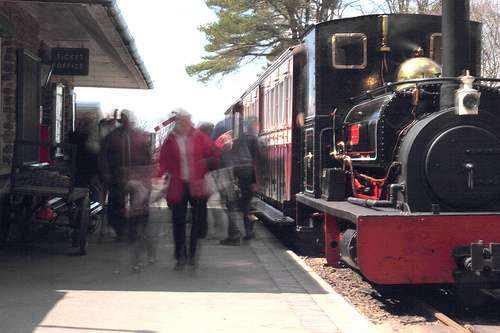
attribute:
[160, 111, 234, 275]
lady — blurred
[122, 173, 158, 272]
child — blurred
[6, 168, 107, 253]
bench — park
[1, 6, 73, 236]
wall — brick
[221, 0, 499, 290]
red — black, locomotive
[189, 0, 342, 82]
tree — tall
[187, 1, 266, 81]
leaves — green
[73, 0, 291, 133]
sky — bright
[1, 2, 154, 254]
building — ticket office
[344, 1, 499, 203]
steam egine — black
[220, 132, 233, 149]
hand — pointing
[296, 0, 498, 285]
train engine — vintage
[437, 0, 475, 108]
smoke stack — black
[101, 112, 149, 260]
pedestrian — blurred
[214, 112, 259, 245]
pedestrian — blurred